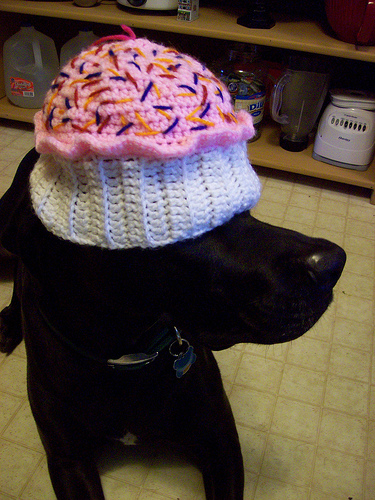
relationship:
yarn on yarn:
[122, 68, 142, 95] [32, 34, 266, 160]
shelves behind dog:
[81, 7, 362, 184] [32, 223, 349, 470]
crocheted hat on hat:
[27, 17, 258, 161] [24, 18, 266, 255]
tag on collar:
[169, 324, 197, 378] [103, 322, 195, 375]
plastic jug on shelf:
[3, 20, 60, 110] [6, 8, 374, 180]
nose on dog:
[294, 238, 347, 291] [1, 149, 347, 494]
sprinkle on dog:
[150, 101, 175, 111] [1, 149, 347, 494]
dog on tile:
[238, 416, 306, 493] [274, 360, 330, 405]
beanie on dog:
[27, 22, 261, 253] [15, 238, 287, 445]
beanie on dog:
[27, 22, 261, 253] [55, 238, 344, 391]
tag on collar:
[172, 347, 197, 380] [32, 300, 174, 371]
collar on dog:
[32, 300, 174, 371] [1, 149, 347, 494]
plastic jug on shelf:
[3, 20, 58, 108] [0, 1, 374, 202]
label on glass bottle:
[233, 94, 264, 121] [207, 41, 264, 142]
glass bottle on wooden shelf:
[207, 41, 264, 142] [245, 129, 370, 180]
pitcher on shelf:
[265, 55, 332, 153] [4, 2, 373, 62]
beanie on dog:
[25, 24, 259, 248] [1, 149, 347, 494]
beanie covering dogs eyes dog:
[27, 22, 261, 253] [1, 149, 347, 494]